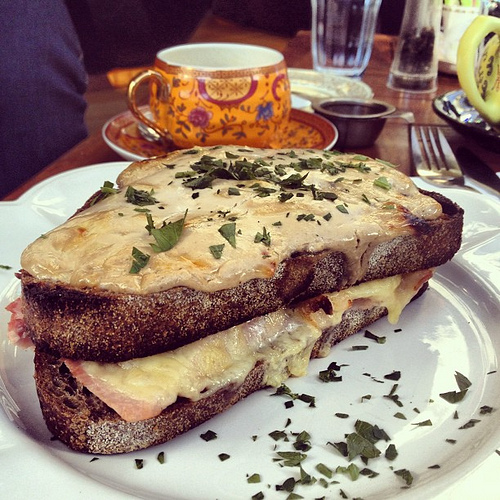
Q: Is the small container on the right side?
A: Yes, the container is on the right of the image.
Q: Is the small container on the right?
A: Yes, the container is on the right of the image.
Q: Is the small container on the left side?
A: No, the container is on the right of the image.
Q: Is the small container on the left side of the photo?
A: No, the container is on the right of the image.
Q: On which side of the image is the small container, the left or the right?
A: The container is on the right of the image.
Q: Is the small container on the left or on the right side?
A: The container is on the right of the image.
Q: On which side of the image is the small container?
A: The container is on the right of the image.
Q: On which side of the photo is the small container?
A: The container is on the right of the image.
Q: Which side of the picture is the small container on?
A: The container is on the right of the image.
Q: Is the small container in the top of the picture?
A: Yes, the container is in the top of the image.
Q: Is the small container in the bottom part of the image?
A: No, the container is in the top of the image.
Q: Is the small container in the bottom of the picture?
A: No, the container is in the top of the image.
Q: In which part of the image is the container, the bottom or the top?
A: The container is in the top of the image.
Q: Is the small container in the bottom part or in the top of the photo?
A: The container is in the top of the image.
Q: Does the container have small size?
A: Yes, the container is small.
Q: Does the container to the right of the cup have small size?
A: Yes, the container is small.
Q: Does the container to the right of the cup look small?
A: Yes, the container is small.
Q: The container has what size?
A: The container is small.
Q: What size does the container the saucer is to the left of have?
A: The container has small size.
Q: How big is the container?
A: The container is small.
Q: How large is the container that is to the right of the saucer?
A: The container is small.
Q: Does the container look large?
A: No, the container is small.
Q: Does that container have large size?
A: No, the container is small.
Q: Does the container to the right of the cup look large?
A: No, the container is small.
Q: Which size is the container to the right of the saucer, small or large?
A: The container is small.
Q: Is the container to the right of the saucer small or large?
A: The container is small.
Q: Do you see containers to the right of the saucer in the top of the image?
A: Yes, there is a container to the right of the saucer.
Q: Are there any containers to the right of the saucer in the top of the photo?
A: Yes, there is a container to the right of the saucer.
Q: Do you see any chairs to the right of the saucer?
A: No, there is a container to the right of the saucer.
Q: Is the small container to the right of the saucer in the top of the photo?
A: Yes, the container is to the right of the saucer.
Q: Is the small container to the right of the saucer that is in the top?
A: Yes, the container is to the right of the saucer.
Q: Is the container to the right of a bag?
A: No, the container is to the right of the saucer.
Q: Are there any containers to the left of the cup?
A: No, the container is to the right of the cup.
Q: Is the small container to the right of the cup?
A: Yes, the container is to the right of the cup.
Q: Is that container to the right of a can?
A: No, the container is to the right of the cup.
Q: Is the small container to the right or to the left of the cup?
A: The container is to the right of the cup.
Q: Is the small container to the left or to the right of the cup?
A: The container is to the right of the cup.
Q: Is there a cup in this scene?
A: Yes, there is a cup.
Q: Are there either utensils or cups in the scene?
A: Yes, there is a cup.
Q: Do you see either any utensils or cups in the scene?
A: Yes, there is a cup.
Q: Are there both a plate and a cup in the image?
A: Yes, there are both a cup and a plate.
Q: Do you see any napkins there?
A: No, there are no napkins.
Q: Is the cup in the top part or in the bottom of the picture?
A: The cup is in the top of the image.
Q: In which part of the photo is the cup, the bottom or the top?
A: The cup is in the top of the image.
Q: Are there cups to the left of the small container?
A: Yes, there is a cup to the left of the container.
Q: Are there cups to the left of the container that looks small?
A: Yes, there is a cup to the left of the container.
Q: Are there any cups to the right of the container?
A: No, the cup is to the left of the container.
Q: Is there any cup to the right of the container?
A: No, the cup is to the left of the container.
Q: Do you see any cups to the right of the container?
A: No, the cup is to the left of the container.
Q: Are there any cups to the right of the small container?
A: No, the cup is to the left of the container.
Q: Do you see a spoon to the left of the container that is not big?
A: No, there is a cup to the left of the container.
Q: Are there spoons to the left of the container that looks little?
A: No, there is a cup to the left of the container.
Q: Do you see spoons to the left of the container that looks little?
A: No, there is a cup to the left of the container.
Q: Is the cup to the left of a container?
A: Yes, the cup is to the left of a container.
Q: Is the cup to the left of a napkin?
A: No, the cup is to the left of a container.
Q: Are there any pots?
A: No, there are no pots.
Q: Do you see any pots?
A: No, there are no pots.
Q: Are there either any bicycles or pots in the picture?
A: No, there are no pots or bicycles.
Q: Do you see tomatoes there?
A: No, there are no tomatoes.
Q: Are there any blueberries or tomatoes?
A: No, there are no tomatoes or blueberries.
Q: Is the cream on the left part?
A: Yes, the cream is on the left of the image.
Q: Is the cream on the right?
A: No, the cream is on the left of the image.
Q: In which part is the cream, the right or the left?
A: The cream is on the left of the image.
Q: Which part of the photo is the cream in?
A: The cream is on the left of the image.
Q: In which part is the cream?
A: The cream is on the left of the image.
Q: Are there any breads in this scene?
A: Yes, there is a bread.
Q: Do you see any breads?
A: Yes, there is a bread.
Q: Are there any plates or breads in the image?
A: Yes, there is a bread.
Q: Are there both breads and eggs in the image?
A: No, there is a bread but no eggs.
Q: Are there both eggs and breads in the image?
A: No, there is a bread but no eggs.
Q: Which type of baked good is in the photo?
A: The baked good is a bread.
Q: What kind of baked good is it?
A: The food is a bread.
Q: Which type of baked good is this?
A: This is a bread.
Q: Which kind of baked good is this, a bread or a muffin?
A: This is a bread.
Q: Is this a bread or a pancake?
A: This is a bread.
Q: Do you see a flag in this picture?
A: No, there are no flags.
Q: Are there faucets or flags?
A: No, there are no flags or faucets.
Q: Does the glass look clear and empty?
A: Yes, the glass is clear and empty.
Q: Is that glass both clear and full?
A: No, the glass is clear but empty.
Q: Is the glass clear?
A: Yes, the glass is clear.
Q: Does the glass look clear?
A: Yes, the glass is clear.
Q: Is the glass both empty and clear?
A: Yes, the glass is empty and clear.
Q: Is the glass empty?
A: Yes, the glass is empty.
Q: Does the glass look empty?
A: Yes, the glass is empty.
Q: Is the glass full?
A: No, the glass is empty.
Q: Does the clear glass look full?
A: No, the glass is empty.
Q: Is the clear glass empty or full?
A: The glass is empty.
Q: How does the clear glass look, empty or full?
A: The glass is empty.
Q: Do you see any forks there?
A: Yes, there is a fork.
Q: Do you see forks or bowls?
A: Yes, there is a fork.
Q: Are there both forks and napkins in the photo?
A: No, there is a fork but no napkins.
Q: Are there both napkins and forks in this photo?
A: No, there is a fork but no napkins.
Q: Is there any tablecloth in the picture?
A: No, there are no tablecloths.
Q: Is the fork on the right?
A: Yes, the fork is on the right of the image.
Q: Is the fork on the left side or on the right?
A: The fork is on the right of the image.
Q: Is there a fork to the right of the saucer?
A: Yes, there is a fork to the right of the saucer.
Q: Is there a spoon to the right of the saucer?
A: No, there is a fork to the right of the saucer.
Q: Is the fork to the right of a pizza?
A: No, the fork is to the right of a saucer.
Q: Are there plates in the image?
A: Yes, there is a plate.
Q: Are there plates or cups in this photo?
A: Yes, there is a plate.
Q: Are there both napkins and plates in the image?
A: No, there is a plate but no napkins.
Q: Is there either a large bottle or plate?
A: Yes, there is a large plate.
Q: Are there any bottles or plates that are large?
A: Yes, the plate is large.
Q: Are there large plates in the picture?
A: Yes, there is a large plate.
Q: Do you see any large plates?
A: Yes, there is a large plate.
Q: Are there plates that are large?
A: Yes, there is a plate that is large.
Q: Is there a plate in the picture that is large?
A: Yes, there is a plate that is large.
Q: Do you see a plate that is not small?
A: Yes, there is a large plate.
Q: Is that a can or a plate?
A: That is a plate.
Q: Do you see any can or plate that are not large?
A: No, there is a plate but it is large.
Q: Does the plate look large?
A: Yes, the plate is large.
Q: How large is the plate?
A: The plate is large.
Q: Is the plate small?
A: No, the plate is large.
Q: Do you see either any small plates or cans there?
A: No, there is a plate but it is large.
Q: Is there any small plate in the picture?
A: No, there is a plate but it is large.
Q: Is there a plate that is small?
A: No, there is a plate but it is large.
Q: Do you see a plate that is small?
A: No, there is a plate but it is large.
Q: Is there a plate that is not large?
A: No, there is a plate but it is large.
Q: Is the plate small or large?
A: The plate is large.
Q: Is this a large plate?
A: Yes, this is a large plate.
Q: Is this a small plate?
A: No, this is a large plate.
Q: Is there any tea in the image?
A: No, there is no tea.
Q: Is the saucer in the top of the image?
A: Yes, the saucer is in the top of the image.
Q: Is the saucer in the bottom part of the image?
A: No, the saucer is in the top of the image.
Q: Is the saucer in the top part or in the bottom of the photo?
A: The saucer is in the top of the image.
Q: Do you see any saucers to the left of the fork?
A: Yes, there is a saucer to the left of the fork.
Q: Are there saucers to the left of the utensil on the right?
A: Yes, there is a saucer to the left of the fork.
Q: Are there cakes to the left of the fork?
A: No, there is a saucer to the left of the fork.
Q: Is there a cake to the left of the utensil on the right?
A: No, there is a saucer to the left of the fork.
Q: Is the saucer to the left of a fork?
A: Yes, the saucer is to the left of a fork.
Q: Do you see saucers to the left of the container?
A: Yes, there is a saucer to the left of the container.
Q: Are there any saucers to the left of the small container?
A: Yes, there is a saucer to the left of the container.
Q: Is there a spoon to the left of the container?
A: No, there is a saucer to the left of the container.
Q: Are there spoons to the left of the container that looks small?
A: No, there is a saucer to the left of the container.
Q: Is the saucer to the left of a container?
A: Yes, the saucer is to the left of a container.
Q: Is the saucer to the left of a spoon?
A: No, the saucer is to the left of a container.